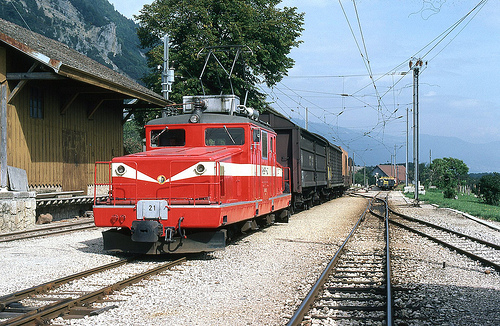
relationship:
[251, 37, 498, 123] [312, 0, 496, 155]
clouds in sky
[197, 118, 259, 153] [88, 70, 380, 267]
left window in train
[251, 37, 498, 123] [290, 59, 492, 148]
clouds in sky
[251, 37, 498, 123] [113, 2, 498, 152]
clouds in sky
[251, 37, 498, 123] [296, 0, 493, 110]
clouds in sky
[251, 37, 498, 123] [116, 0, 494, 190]
clouds in sky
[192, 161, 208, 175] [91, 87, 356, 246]
light of train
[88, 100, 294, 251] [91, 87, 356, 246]
front of train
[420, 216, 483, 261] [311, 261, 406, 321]
tracks crossing tracks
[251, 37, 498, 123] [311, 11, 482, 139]
clouds in sky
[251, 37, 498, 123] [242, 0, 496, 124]
clouds in sky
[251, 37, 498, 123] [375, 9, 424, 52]
clouds in sky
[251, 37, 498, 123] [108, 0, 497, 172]
clouds in sky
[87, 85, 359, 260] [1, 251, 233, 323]
train on tracks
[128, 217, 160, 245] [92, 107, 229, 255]
attachment on train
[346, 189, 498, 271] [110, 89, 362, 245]
tracks are train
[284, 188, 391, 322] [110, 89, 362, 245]
tracks are train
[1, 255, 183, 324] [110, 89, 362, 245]
tracks are train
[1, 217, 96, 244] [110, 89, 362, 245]
tracks are train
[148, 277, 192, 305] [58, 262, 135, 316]
rocks are on train tracks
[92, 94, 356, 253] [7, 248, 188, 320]
train on track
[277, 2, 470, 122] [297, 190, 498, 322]
power lines by train tracks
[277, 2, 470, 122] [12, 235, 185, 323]
power lines by train tracks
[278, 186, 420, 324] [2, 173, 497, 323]
tracks are parallel to tracks